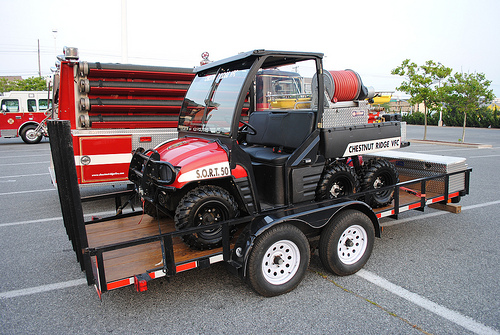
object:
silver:
[323, 101, 368, 129]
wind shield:
[177, 55, 261, 136]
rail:
[82, 169, 471, 257]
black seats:
[239, 110, 315, 166]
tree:
[390, 60, 455, 140]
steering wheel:
[239, 120, 257, 136]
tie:
[399, 186, 421, 197]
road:
[0, 123, 499, 334]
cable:
[329, 71, 357, 103]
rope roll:
[311, 69, 362, 102]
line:
[354, 269, 500, 335]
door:
[0, 99, 18, 136]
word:
[349, 143, 374, 153]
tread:
[358, 157, 383, 182]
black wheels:
[174, 186, 240, 250]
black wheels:
[316, 165, 361, 201]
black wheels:
[356, 158, 399, 208]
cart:
[45, 47, 471, 301]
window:
[27, 99, 36, 112]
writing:
[196, 167, 228, 179]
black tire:
[319, 210, 375, 277]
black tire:
[248, 224, 310, 298]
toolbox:
[362, 150, 467, 193]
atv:
[128, 49, 408, 249]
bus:
[0, 91, 53, 145]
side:
[325, 121, 401, 158]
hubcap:
[262, 240, 300, 285]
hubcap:
[337, 224, 368, 265]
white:
[177, 162, 230, 183]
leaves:
[404, 74, 483, 92]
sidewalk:
[406, 125, 499, 143]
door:
[233, 53, 322, 215]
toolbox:
[323, 101, 368, 128]